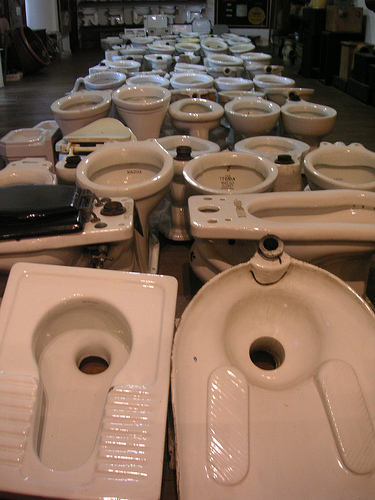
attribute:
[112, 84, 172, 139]
toilet bowl — tall, white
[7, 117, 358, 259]
toilets — white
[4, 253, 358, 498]
toilets — white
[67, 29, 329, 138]
toilet bowls — in many shapes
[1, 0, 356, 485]
toilet bowls — in many sizes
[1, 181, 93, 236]
lid — black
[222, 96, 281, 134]
toilet bowl — white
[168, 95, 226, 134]
toilet bowl — cream colored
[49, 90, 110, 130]
toilet bowl — round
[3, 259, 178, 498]
toilet bowl — white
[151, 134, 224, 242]
toilet bowl — white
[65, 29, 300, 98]
toilets — variety, white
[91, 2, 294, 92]
toilets — white, variety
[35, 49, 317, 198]
toilets — white, variety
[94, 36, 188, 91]
toilets — variety, white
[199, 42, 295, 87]
toilets — white, variety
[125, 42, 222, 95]
toilets — variety, white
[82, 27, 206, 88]
toilets — white, variety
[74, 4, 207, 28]
toilets — variety, white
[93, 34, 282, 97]
toilets — white, variety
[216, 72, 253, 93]
toilet bowl — white